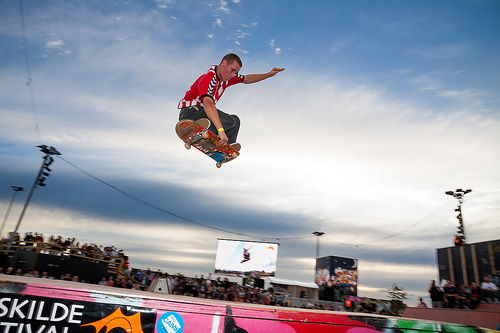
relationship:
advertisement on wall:
[153, 309, 186, 332] [0, 270, 499, 333]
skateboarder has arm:
[173, 50, 289, 172] [228, 64, 287, 89]